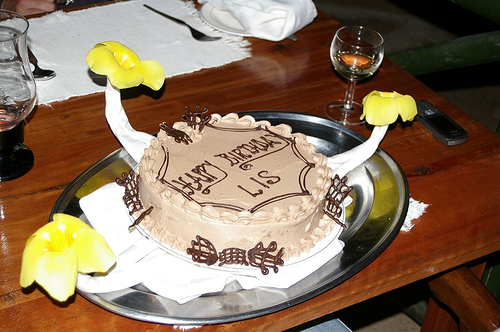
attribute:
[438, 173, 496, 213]
table — blown, wooden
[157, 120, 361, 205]
cake — circular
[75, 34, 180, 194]
flower — yellow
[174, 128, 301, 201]
lettering — black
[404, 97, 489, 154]
cellphone — gray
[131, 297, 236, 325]
silver platter — shiny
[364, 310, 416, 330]
carpet — grey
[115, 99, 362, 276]
cake — chocolate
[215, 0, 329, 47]
napkin — white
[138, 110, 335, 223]
ribbon — chocolate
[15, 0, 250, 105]
cloth — white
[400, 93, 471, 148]
cell phone — grey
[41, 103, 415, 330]
pan — metal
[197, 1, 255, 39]
plate — white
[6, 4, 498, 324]
table — brown